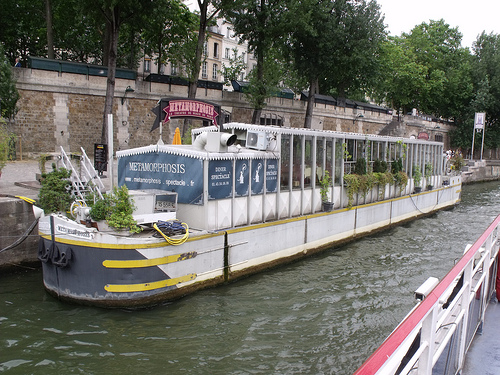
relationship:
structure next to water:
[38, 121, 462, 309] [0, 178, 498, 374]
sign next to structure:
[164, 98, 221, 126] [38, 121, 462, 309]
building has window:
[133, 11, 222, 84] [214, 43, 220, 60]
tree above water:
[55, 0, 197, 145] [0, 178, 498, 374]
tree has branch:
[55, 0, 197, 145] [96, 4, 117, 29]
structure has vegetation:
[38, 121, 462, 309] [94, 187, 145, 234]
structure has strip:
[38, 121, 462, 309] [38, 231, 156, 251]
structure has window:
[38, 121, 462, 309] [280, 133, 293, 190]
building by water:
[133, 11, 222, 84] [0, 178, 498, 374]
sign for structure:
[164, 98, 221, 126] [38, 121, 462, 309]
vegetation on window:
[321, 173, 329, 199] [315, 137, 324, 186]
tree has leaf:
[55, 0, 197, 145] [134, 15, 135, 17]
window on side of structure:
[280, 133, 293, 190] [38, 121, 462, 309]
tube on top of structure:
[194, 131, 236, 151] [38, 121, 462, 309]